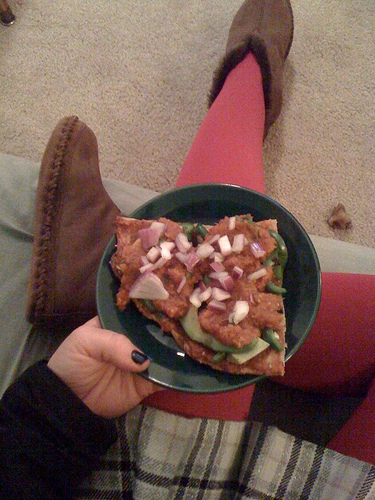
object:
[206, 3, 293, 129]
shoes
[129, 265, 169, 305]
onions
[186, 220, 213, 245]
peppers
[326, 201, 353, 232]
nose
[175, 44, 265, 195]
leggings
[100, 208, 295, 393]
pizza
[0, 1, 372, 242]
carpet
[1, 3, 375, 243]
floor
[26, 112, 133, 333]
slipper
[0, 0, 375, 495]
woman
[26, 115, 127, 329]
foot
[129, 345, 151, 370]
finernail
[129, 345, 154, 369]
polish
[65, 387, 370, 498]
couch material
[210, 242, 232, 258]
onions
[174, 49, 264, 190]
tights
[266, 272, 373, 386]
leg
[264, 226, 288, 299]
peppers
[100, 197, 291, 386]
food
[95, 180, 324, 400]
plate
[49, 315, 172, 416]
hand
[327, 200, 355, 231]
item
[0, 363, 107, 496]
sleeve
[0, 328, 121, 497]
sweater